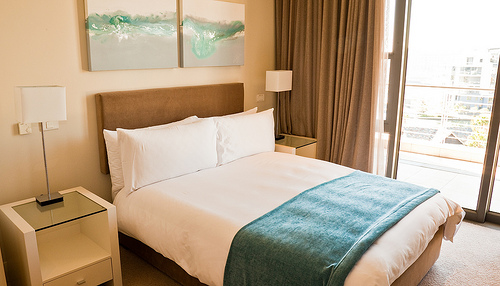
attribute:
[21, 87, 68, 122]
shade of lamp — white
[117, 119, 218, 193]
pillow — white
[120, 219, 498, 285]
carpet — ground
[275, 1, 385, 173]
curtain — brown, open, beige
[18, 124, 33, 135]
light switch — white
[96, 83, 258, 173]
head board — brown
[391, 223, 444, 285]
foot board — brown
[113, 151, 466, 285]
linen — white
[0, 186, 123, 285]
nightstand — white